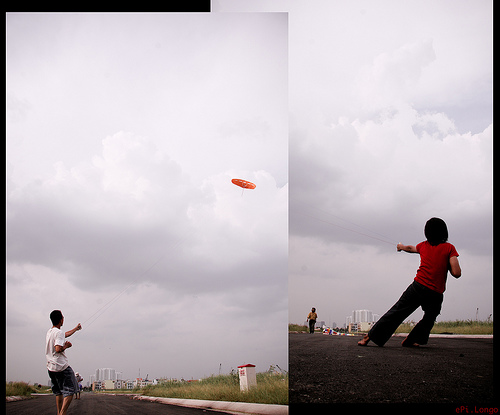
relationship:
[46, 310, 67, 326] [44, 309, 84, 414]
head of man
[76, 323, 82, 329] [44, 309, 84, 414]
hand of man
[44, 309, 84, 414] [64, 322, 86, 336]
man has arm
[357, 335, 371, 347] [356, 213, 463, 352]
foot of man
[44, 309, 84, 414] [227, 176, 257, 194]
man flying kite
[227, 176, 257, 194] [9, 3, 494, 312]
kite in sky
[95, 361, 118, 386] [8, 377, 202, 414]
building at end of road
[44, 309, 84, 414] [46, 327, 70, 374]
man wearing shirt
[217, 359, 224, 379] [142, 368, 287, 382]
crane on skyline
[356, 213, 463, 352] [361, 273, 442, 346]
man wearing pants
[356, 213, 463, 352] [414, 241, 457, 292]
man wearing shirt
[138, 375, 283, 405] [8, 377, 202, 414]
grass next to road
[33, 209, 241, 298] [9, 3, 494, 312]
cloud in sky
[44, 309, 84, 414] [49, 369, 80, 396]
man wearing shorts